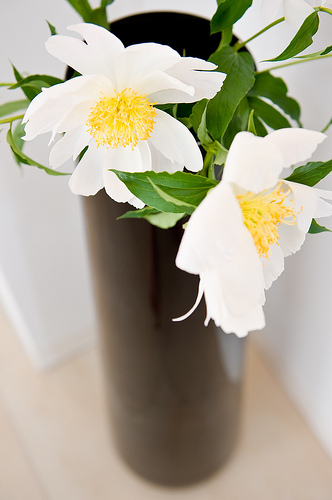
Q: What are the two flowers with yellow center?
A: White.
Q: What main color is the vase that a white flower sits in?
A: Black.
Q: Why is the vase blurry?
A: It's not in focus.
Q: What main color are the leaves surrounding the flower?
A: Green.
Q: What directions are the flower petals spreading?
A: All directions.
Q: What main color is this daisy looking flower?
A: White.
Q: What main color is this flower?
A: White.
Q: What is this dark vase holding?
A: Flowers.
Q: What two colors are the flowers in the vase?
A: White and orange.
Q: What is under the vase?
A: Wood.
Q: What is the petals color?
A: White.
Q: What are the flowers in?
A: Vase.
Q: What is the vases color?
A: Brown.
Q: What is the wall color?
A: White.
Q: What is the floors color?
A: Tan.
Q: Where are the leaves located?
A: Vase.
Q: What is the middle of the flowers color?
A: Yellow.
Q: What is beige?
A: Floor.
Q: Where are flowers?
A: In a vase.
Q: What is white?
A: Flowers.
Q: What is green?
A: Leaves.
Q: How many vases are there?
A: One.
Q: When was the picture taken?
A: Daytime.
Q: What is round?
A: Vase.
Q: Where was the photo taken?
A: Close to a vase.